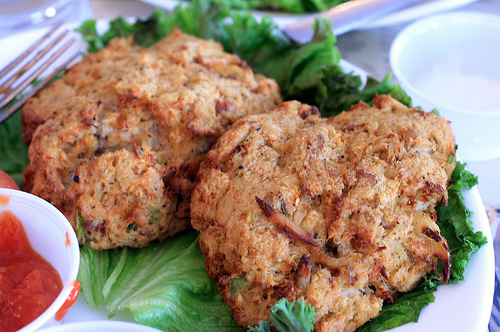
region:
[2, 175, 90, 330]
White container with red sauce.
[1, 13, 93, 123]
A metal four prong fork.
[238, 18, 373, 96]
Lettuce on a plate.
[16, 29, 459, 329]
A meal on a plate.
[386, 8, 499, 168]
empty white container.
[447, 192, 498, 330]
White ceramic dish.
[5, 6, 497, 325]
a plate of food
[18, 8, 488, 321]
bib of lettuce on plate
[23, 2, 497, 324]
the lettuce is green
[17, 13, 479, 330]
two crab cakes on plate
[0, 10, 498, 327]
the plate is white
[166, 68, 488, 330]
the crab cake is brown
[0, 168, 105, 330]
a white cup of sauce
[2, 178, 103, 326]
the sauce is red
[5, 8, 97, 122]
fork on a plate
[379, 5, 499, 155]
a clear plastic cup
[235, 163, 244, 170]
black spot on food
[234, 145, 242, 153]
black spot on food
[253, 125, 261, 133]
black spot on food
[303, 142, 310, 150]
black spot on food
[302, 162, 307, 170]
black spot on food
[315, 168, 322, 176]
black spot on food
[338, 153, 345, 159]
black spot on food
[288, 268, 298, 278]
black spot on food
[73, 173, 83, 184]
black spot on food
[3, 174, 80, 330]
Sauce is in the cup.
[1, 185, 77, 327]
The cup is plastic.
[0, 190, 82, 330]
The sauce is red.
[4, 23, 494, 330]
Food is on the plate.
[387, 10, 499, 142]
A plastic cup is by the plate.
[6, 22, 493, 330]
The lettuce is under other food.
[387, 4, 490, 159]
One cup is empty.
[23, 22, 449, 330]
Two food items are on lettuce.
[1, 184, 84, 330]
Sauce is on the side of the cup.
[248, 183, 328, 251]
the burnt place of the food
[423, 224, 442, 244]
the burnt place of the food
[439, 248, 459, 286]
the burnt place of the food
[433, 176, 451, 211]
the burnt place of the food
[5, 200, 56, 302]
ketchup in the bowl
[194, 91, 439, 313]
pattie on the plate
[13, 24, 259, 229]
patty on the plate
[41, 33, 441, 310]
two pattys on a lettuce leaf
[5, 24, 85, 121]
fork on the plate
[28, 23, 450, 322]
food on a white plate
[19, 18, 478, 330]
plate on the table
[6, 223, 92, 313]
ketchup on the plate